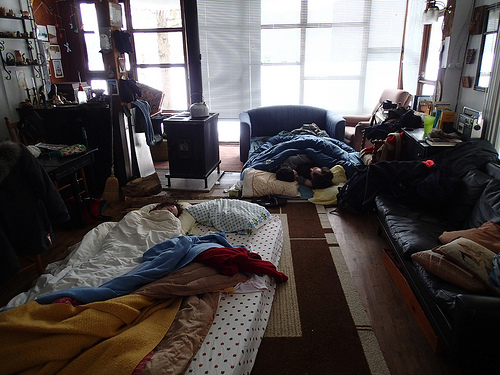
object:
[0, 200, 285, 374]
mattress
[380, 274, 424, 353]
floor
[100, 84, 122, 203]
broom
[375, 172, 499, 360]
couch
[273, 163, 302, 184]
person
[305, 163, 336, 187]
person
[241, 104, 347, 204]
pull out chair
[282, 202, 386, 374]
rug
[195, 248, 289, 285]
blanket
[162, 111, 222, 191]
stove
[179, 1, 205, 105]
smoke pipe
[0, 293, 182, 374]
blanket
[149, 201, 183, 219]
person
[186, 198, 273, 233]
pillow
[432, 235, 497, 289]
pillows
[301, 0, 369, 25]
windows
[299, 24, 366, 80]
windows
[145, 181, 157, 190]
wood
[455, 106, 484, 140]
radio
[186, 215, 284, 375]
sheet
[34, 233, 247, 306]
blanket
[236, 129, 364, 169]
blanket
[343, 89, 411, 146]
chair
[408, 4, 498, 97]
corner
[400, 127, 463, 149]
desk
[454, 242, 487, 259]
ducks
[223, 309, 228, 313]
print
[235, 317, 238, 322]
print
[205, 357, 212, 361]
print